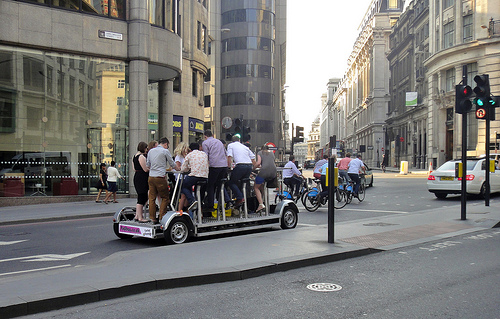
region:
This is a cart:
[96, 175, 314, 247]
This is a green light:
[471, 65, 499, 217]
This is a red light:
[451, 72, 477, 224]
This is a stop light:
[286, 115, 313, 207]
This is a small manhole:
[294, 273, 348, 300]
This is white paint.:
[0, 237, 105, 269]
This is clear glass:
[0, 62, 115, 129]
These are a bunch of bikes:
[273, 173, 390, 220]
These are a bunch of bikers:
[277, 147, 370, 212]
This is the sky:
[302, 19, 334, 56]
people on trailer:
[70, 110, 322, 295]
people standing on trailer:
[125, 127, 177, 239]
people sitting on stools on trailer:
[182, 111, 302, 238]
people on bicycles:
[274, 135, 388, 239]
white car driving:
[422, 132, 499, 212]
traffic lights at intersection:
[435, 65, 499, 255]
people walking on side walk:
[71, 130, 134, 220]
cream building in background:
[306, 6, 498, 173]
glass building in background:
[0, 5, 203, 255]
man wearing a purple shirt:
[193, 120, 240, 190]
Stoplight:
[475, 69, 492, 121]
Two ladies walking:
[91, 159, 118, 206]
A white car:
[428, 153, 498, 200]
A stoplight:
[452, 81, 472, 225]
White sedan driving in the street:
[426, 153, 498, 195]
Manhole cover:
[308, 279, 343, 294]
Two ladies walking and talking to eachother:
[93, 158, 120, 203]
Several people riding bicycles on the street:
[274, 149, 370, 213]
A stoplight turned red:
[453, 84, 470, 219]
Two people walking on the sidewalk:
[93, 158, 120, 203]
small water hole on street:
[305, 276, 356, 306]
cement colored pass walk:
[180, 250, 295, 265]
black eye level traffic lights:
[456, 66, 498, 212]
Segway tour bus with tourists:
[110, 174, 319, 225]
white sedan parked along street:
[422, 157, 489, 193]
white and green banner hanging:
[400, 91, 419, 109]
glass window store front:
[31, 75, 123, 146]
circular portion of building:
[228, 10, 279, 133]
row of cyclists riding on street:
[295, 155, 373, 190]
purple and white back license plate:
[114, 218, 154, 247]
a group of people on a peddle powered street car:
[105, 125, 301, 247]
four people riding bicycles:
[304, 148, 372, 211]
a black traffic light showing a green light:
[470, 70, 499, 125]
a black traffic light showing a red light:
[452, 64, 474, 119]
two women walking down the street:
[94, 160, 124, 210]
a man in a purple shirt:
[200, 125, 230, 217]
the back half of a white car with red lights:
[422, 153, 499, 202]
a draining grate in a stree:
[296, 271, 351, 301]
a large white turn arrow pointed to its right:
[0, 248, 93, 267]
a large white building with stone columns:
[335, 0, 395, 165]